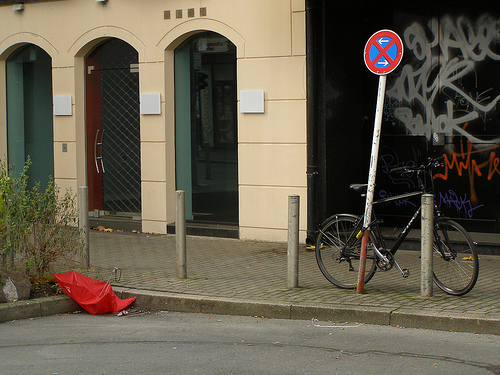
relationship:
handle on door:
[90, 121, 108, 176] [61, 34, 173, 269]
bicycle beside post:
[305, 163, 487, 299] [416, 187, 435, 297]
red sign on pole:
[359, 28, 406, 75] [353, 74, 387, 292]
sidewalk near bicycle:
[1, 214, 500, 323] [313, 155, 481, 298]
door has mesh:
[68, 32, 142, 230] [104, 36, 140, 210]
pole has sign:
[349, 27, 406, 295] [357, 23, 408, 80]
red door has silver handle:
[79, 56, 107, 211] [92, 124, 107, 180]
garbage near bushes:
[2, 242, 129, 330] [0, 154, 92, 303]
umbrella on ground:
[28, 233, 193, 373] [76, 279, 357, 360]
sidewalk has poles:
[43, 159, 492, 320] [154, 197, 330, 294]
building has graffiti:
[332, 31, 497, 272] [377, 14, 499, 218]